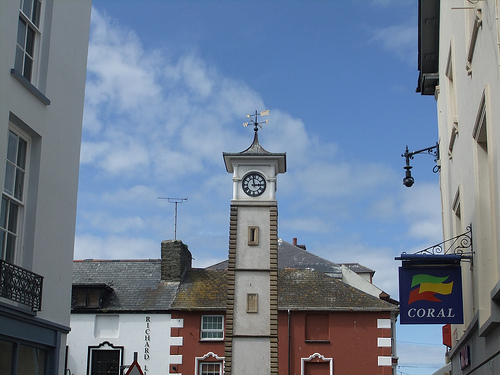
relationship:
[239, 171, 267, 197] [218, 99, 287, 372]
clock on tower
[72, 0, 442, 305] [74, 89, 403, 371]
weather on a building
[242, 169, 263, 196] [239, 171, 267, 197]
hands of a clock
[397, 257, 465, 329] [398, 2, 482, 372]
sign on a building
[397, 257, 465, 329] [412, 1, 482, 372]
sign attached to a building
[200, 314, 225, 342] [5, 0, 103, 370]
window on a building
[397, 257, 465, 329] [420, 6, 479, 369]
sign on wall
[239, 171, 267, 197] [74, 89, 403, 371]
clock on building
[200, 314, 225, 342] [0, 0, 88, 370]
window on side of building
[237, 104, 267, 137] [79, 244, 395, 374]
compass on top of building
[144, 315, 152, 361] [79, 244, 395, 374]
word richard on building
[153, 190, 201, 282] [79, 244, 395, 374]
chimney to building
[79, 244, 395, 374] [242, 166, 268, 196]
building with a clock tower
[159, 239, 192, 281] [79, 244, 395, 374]
chimney on top of building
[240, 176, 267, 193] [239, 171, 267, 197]
face of a clock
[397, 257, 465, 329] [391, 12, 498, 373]
sign hanging on building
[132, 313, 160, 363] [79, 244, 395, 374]
word richard on building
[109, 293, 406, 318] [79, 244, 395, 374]
balcony on building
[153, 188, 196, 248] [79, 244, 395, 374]
antenna on building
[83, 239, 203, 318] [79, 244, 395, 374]
roof of a building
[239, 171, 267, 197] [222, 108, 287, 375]
clock of a clock tower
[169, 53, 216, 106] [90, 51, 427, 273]
cloud iin sky